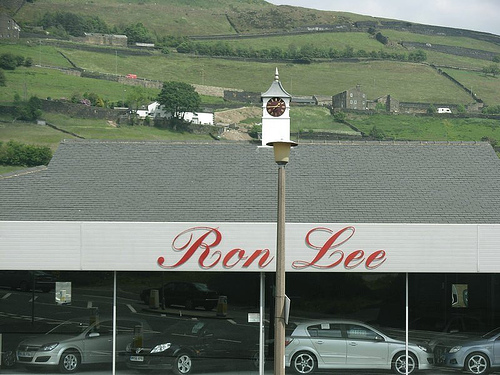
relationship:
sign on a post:
[281, 291, 292, 326] [272, 161, 288, 374]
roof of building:
[2, 138, 499, 221] [2, 138, 499, 368]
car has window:
[281, 317, 439, 375] [304, 320, 384, 343]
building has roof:
[2, 138, 499, 368] [2, 138, 499, 221]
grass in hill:
[3, 4, 499, 148] [8, 2, 499, 106]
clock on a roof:
[265, 92, 288, 118] [2, 138, 499, 221]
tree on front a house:
[151, 75, 204, 128] [134, 97, 220, 128]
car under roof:
[12, 316, 139, 375] [2, 138, 499, 221]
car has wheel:
[281, 317, 439, 375] [289, 347, 422, 374]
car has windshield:
[281, 317, 439, 375] [366, 319, 397, 339]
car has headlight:
[12, 316, 139, 375] [14, 340, 59, 351]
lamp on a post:
[262, 140, 299, 168] [272, 161, 288, 374]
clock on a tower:
[265, 92, 288, 118] [257, 61, 295, 148]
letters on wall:
[153, 225, 389, 276] [120, 107, 380, 275]